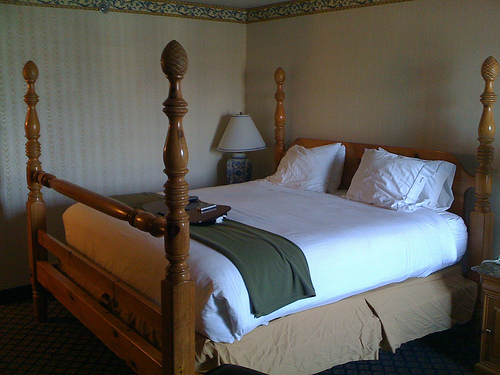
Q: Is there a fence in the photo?
A: No, there are no fences.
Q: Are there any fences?
A: No, there are no fences.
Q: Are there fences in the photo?
A: No, there are no fences.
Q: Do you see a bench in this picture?
A: No, there are no benches.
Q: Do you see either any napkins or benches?
A: No, there are no benches or napkins.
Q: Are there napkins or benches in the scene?
A: No, there are no benches or napkins.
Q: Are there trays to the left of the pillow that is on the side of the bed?
A: Yes, there is a tray to the left of the pillow.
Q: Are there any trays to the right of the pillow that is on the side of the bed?
A: No, the tray is to the left of the pillow.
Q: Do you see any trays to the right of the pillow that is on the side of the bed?
A: No, the tray is to the left of the pillow.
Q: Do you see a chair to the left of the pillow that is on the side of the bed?
A: No, there is a tray to the left of the pillow.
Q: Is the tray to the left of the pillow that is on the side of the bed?
A: Yes, the tray is to the left of the pillow.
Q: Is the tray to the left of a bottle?
A: No, the tray is to the left of the pillow.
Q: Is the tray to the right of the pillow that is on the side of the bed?
A: No, the tray is to the left of the pillow.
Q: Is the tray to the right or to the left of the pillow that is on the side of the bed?
A: The tray is to the left of the pillow.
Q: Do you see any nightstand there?
A: Yes, there is a nightstand.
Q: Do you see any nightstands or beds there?
A: Yes, there is a nightstand.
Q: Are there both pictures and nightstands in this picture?
A: No, there is a nightstand but no pictures.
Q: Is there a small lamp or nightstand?
A: Yes, there is a small nightstand.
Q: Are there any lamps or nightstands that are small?
A: Yes, the nightstand is small.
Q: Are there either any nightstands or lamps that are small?
A: Yes, the nightstand is small.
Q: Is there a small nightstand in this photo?
A: Yes, there is a small nightstand.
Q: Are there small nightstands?
A: Yes, there is a small nightstand.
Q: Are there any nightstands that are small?
A: Yes, there is a nightstand that is small.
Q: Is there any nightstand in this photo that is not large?
A: Yes, there is a small nightstand.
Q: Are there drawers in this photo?
A: No, there are no drawers.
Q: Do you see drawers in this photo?
A: No, there are no drawers.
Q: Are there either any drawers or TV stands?
A: No, there are no drawers or TV stands.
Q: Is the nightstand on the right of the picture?
A: Yes, the nightstand is on the right of the image.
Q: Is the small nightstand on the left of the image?
A: No, the nightstand is on the right of the image.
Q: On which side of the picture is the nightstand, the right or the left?
A: The nightstand is on the right of the image.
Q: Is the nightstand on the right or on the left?
A: The nightstand is on the right of the image.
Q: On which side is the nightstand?
A: The nightstand is on the right of the image.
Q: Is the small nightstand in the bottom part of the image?
A: Yes, the nightstand is in the bottom of the image.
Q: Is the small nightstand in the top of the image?
A: No, the nightstand is in the bottom of the image.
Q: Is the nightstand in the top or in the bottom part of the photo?
A: The nightstand is in the bottom of the image.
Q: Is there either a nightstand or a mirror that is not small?
A: No, there is a nightstand but it is small.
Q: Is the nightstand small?
A: Yes, the nightstand is small.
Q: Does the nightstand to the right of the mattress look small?
A: Yes, the nightstand is small.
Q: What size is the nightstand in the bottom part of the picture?
A: The nightstand is small.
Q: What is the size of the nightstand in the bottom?
A: The nightstand is small.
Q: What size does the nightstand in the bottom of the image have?
A: The nightstand has small size.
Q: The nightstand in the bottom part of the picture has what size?
A: The nightstand is small.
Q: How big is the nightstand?
A: The nightstand is small.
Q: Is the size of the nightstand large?
A: No, the nightstand is small.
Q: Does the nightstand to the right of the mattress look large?
A: No, the nightstand is small.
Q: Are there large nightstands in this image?
A: No, there is a nightstand but it is small.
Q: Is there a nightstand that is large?
A: No, there is a nightstand but it is small.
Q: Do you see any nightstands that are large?
A: No, there is a nightstand but it is small.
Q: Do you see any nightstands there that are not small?
A: No, there is a nightstand but it is small.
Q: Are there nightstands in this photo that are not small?
A: No, there is a nightstand but it is small.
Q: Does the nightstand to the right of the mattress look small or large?
A: The nightstand is small.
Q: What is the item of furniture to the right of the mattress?
A: The piece of furniture is a nightstand.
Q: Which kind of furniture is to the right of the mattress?
A: The piece of furniture is a nightstand.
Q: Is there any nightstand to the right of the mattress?
A: Yes, there is a nightstand to the right of the mattress.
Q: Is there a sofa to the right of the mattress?
A: No, there is a nightstand to the right of the mattress.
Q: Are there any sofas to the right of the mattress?
A: No, there is a nightstand to the right of the mattress.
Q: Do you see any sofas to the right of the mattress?
A: No, there is a nightstand to the right of the mattress.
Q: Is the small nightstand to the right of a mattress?
A: Yes, the nightstand is to the right of a mattress.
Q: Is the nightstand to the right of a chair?
A: No, the nightstand is to the right of a mattress.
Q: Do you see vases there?
A: No, there are no vases.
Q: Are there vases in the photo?
A: No, there are no vases.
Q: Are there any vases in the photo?
A: No, there are no vases.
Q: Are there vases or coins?
A: No, there are no vases or coins.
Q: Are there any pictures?
A: No, there are no pictures.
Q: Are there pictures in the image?
A: No, there are no pictures.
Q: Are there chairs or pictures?
A: No, there are no pictures or chairs.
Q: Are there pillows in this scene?
A: Yes, there is a pillow.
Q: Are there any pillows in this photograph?
A: Yes, there is a pillow.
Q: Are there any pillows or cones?
A: Yes, there is a pillow.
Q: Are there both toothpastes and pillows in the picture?
A: No, there is a pillow but no toothpastes.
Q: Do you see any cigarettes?
A: No, there are no cigarettes.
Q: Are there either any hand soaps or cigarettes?
A: No, there are no cigarettes or hand soaps.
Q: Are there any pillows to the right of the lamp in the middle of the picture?
A: Yes, there is a pillow to the right of the lamp.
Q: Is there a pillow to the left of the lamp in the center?
A: No, the pillow is to the right of the lamp.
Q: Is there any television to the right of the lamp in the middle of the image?
A: No, there is a pillow to the right of the lamp.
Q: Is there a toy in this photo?
A: No, there are no toys.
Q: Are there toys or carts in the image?
A: No, there are no toys or carts.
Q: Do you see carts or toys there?
A: No, there are no toys or carts.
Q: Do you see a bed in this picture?
A: Yes, there is a bed.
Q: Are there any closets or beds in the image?
A: Yes, there is a bed.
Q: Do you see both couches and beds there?
A: No, there is a bed but no couches.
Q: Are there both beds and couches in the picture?
A: No, there is a bed but no couches.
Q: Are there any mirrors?
A: No, there are no mirrors.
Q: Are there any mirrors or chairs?
A: No, there are no mirrors or chairs.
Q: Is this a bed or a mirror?
A: This is a bed.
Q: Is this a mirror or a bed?
A: This is a bed.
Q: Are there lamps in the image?
A: Yes, there is a lamp.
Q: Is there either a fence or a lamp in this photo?
A: Yes, there is a lamp.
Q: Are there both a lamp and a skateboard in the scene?
A: No, there is a lamp but no skateboards.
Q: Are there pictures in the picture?
A: No, there are no pictures.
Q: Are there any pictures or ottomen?
A: No, there are no pictures or ottomen.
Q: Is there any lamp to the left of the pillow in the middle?
A: Yes, there is a lamp to the left of the pillow.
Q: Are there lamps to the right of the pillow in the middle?
A: No, the lamp is to the left of the pillow.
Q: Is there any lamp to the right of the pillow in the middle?
A: No, the lamp is to the left of the pillow.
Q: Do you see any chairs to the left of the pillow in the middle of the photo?
A: No, there is a lamp to the left of the pillow.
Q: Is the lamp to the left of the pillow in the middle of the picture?
A: Yes, the lamp is to the left of the pillow.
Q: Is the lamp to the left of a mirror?
A: No, the lamp is to the left of the pillow.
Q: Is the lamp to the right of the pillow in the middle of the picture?
A: No, the lamp is to the left of the pillow.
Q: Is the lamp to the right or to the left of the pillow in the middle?
A: The lamp is to the left of the pillow.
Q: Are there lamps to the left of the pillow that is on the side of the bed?
A: Yes, there is a lamp to the left of the pillow.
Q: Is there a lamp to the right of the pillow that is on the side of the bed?
A: No, the lamp is to the left of the pillow.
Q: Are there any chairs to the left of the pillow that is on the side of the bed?
A: No, there is a lamp to the left of the pillow.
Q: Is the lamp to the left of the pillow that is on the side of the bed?
A: Yes, the lamp is to the left of the pillow.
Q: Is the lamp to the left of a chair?
A: No, the lamp is to the left of the pillow.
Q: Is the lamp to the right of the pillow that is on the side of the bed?
A: No, the lamp is to the left of the pillow.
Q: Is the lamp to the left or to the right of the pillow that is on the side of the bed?
A: The lamp is to the left of the pillow.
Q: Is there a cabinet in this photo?
A: Yes, there is a cabinet.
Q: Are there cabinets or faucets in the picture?
A: Yes, there is a cabinet.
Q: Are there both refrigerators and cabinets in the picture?
A: No, there is a cabinet but no refrigerators.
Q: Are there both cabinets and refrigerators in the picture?
A: No, there is a cabinet but no refrigerators.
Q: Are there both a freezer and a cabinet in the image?
A: No, there is a cabinet but no refrigerators.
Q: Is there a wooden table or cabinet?
A: Yes, there is a wood cabinet.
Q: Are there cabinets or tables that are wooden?
A: Yes, the cabinet is wooden.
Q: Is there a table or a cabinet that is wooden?
A: Yes, the cabinet is wooden.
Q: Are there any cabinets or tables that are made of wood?
A: Yes, the cabinet is made of wood.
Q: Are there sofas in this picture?
A: No, there are no sofas.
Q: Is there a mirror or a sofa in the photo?
A: No, there are no sofas or mirrors.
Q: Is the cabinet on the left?
A: Yes, the cabinet is on the left of the image.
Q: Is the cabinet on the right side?
A: No, the cabinet is on the left of the image.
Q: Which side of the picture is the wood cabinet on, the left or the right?
A: The cabinet is on the left of the image.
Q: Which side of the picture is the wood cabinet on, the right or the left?
A: The cabinet is on the left of the image.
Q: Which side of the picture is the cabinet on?
A: The cabinet is on the left of the image.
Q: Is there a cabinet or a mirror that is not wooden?
A: No, there is a cabinet but it is wooden.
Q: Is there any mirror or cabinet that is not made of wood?
A: No, there is a cabinet but it is made of wood.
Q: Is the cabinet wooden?
A: Yes, the cabinet is wooden.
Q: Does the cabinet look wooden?
A: Yes, the cabinet is wooden.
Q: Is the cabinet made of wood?
A: Yes, the cabinet is made of wood.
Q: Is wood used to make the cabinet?
A: Yes, the cabinet is made of wood.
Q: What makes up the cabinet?
A: The cabinet is made of wood.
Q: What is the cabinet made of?
A: The cabinet is made of wood.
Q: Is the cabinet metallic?
A: No, the cabinet is wooden.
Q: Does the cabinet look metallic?
A: No, the cabinet is wooden.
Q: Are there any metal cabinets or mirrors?
A: No, there is a cabinet but it is wooden.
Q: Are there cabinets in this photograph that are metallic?
A: No, there is a cabinet but it is wooden.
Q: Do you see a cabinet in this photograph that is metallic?
A: No, there is a cabinet but it is wooden.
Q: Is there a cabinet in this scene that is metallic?
A: No, there is a cabinet but it is wooden.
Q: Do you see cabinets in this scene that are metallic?
A: No, there is a cabinet but it is wooden.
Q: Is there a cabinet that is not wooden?
A: No, there is a cabinet but it is wooden.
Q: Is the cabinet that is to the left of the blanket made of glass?
A: No, the cabinet is made of wood.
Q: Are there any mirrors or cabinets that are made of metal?
A: No, there is a cabinet but it is made of wood.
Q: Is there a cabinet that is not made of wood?
A: No, there is a cabinet but it is made of wood.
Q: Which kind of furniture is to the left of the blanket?
A: The piece of furniture is a cabinet.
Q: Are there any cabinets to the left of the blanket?
A: Yes, there is a cabinet to the left of the blanket.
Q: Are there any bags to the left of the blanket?
A: No, there is a cabinet to the left of the blanket.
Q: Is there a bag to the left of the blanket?
A: No, there is a cabinet to the left of the blanket.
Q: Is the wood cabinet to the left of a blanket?
A: Yes, the cabinet is to the left of a blanket.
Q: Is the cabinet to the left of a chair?
A: No, the cabinet is to the left of a blanket.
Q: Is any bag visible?
A: No, there are no bags.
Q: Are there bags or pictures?
A: No, there are no bags or pictures.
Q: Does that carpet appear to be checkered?
A: Yes, the carpet is checkered.